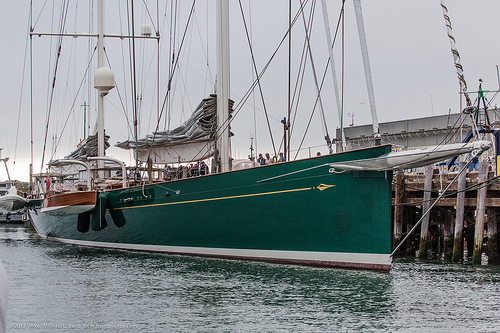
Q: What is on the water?
A: Sailboat.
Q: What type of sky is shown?
A: Grey cloudy.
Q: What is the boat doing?
A: Docked.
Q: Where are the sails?
A: Down.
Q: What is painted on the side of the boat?
A: Yellow arrow.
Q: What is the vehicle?
A: Boat.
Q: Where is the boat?
A: In the water.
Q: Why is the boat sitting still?
A: Tied at the dock.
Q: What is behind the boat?
A: Dock.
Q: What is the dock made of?
A: Wood.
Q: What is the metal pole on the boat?
A: Mast.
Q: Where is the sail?
A: Retracted.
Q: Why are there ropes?
A: To tie the sails.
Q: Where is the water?
A: Under the boat.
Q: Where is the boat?
A: In the harbour.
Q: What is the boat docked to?
A: The pier.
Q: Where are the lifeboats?
A: On the right of the large boat.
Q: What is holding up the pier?
A: Wooden columns.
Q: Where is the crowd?
A: On the pier.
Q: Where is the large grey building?
A: Top right corner of picture?.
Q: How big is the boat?
A: Large.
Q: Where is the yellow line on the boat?
A: On top half of hull.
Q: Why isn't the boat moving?
A: It is docked.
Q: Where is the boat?
A: In the water.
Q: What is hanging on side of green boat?
A: A small boat.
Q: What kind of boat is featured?
A: A sailing boat.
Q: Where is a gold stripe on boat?
A: Along the side.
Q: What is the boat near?
A: A dock.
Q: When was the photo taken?
A: In the daytime.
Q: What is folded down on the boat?
A: Sails.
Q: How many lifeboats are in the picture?
A: One.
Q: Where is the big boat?
A: In the water.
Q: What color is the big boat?
A: Green.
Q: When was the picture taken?
A: During the day.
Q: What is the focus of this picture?
A: A big boat.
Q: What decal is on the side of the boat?
A: An arrow.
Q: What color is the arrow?
A: Yellow.